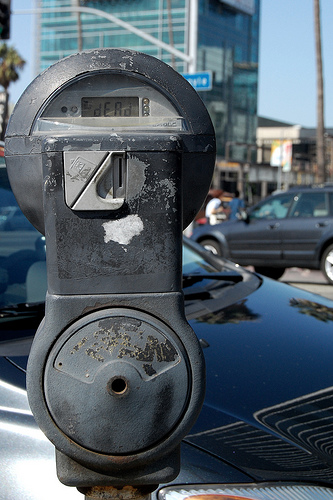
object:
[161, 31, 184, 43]
window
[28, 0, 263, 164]
building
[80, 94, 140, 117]
screen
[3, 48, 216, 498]
meter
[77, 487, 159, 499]
post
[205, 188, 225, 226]
people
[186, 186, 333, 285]
car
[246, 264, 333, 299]
street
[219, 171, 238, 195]
window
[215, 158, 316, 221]
building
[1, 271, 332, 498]
hood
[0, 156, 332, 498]
car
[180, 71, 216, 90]
street sign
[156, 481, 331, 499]
headlight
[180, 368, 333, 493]
reflection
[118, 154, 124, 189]
coin slot